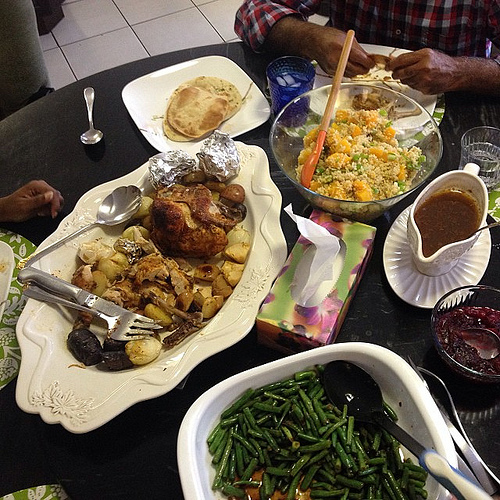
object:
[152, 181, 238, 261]
chicken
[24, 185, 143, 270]
spoon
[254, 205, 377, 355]
tissue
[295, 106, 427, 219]
stuffing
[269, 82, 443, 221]
bowl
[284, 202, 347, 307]
tissue piece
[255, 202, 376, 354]
box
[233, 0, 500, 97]
person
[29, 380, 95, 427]
design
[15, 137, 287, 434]
white plate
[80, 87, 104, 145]
spoon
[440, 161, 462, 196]
ground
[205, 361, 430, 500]
spoon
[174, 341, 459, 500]
bowl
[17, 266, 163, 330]
knife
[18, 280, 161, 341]
fork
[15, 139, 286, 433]
dish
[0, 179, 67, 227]
hand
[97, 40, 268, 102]
plate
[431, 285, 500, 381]
cup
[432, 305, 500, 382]
grape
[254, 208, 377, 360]
napkin box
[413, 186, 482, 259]
brown gravy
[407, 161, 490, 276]
gravy boat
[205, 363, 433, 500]
beans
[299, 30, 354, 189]
tablespoon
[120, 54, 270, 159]
bread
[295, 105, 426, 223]
quinoa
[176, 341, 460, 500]
white pot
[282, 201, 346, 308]
kleenex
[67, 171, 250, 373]
eating chicken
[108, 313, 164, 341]
fork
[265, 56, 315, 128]
glass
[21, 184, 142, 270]
utensils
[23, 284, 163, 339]
utensils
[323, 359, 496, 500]
utensils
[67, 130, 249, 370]
food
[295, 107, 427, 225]
food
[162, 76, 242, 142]
food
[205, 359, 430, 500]
food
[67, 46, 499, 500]
meal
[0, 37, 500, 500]
table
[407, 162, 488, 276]
bowl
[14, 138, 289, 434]
plate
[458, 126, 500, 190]
glass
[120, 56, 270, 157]
platter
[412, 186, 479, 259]
gravy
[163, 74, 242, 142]
patty